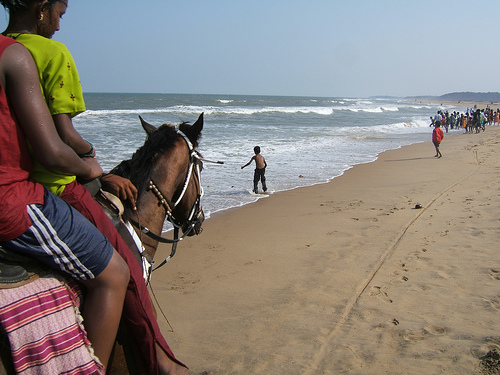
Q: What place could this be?
A: It is a beach.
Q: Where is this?
A: This is at the beach.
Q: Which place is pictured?
A: It is a beach.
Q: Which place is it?
A: It is a beach.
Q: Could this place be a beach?
A: Yes, it is a beach.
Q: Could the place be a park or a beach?
A: It is a beach.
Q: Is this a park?
A: No, it is a beach.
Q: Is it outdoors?
A: Yes, it is outdoors.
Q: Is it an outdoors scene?
A: Yes, it is outdoors.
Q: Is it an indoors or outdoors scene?
A: It is outdoors.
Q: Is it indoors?
A: No, it is outdoors.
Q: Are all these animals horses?
A: Yes, all the animals are horses.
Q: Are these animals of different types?
A: No, all the animals are horses.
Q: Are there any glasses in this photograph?
A: No, there are no glasses.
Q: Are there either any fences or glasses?
A: No, there are no glasses or fences.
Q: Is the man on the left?
A: Yes, the man is on the left of the image.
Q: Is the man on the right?
A: No, the man is on the left of the image.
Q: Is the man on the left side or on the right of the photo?
A: The man is on the left of the image.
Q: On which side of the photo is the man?
A: The man is on the left of the image.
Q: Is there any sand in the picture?
A: Yes, there is sand.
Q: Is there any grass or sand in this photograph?
A: Yes, there is sand.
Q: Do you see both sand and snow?
A: No, there is sand but no snow.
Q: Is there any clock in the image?
A: No, there are no clocks.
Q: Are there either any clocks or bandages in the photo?
A: No, there are no clocks or bandages.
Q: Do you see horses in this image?
A: Yes, there is a horse.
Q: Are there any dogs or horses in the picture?
A: Yes, there is a horse.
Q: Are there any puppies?
A: No, there are no puppies.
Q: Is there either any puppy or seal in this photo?
A: No, there are no puppies or seals.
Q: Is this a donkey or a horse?
A: This is a horse.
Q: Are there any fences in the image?
A: No, there are no fences.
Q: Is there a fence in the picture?
A: No, there are no fences.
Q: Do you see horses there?
A: Yes, there is a horse.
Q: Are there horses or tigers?
A: Yes, there is a horse.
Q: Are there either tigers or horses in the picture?
A: Yes, there is a horse.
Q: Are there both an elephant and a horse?
A: No, there is a horse but no elephants.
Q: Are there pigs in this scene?
A: No, there are no pigs.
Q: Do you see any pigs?
A: No, there are no pigs.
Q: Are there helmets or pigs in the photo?
A: No, there are no pigs or helmets.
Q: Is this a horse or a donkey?
A: This is a horse.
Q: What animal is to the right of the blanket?
A: The animal is a horse.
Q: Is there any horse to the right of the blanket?
A: Yes, there is a horse to the right of the blanket.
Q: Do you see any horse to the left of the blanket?
A: No, the horse is to the right of the blanket.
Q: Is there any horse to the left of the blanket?
A: No, the horse is to the right of the blanket.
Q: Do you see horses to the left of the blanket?
A: No, the horse is to the right of the blanket.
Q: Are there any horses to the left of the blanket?
A: No, the horse is to the right of the blanket.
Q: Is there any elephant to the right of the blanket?
A: No, there is a horse to the right of the blanket.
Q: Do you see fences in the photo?
A: No, there are no fences.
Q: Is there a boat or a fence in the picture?
A: No, there are no fences or boats.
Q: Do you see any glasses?
A: No, there are no glasses.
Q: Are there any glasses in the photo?
A: No, there are no glasses.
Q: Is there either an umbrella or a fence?
A: No, there are no fences or umbrellas.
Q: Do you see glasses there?
A: No, there are no glasses.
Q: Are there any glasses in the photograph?
A: No, there are no glasses.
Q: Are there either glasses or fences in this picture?
A: No, there are no glasses or fences.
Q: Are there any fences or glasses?
A: No, there are no glasses or fences.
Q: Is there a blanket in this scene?
A: Yes, there is a blanket.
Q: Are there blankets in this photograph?
A: Yes, there is a blanket.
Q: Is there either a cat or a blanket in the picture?
A: Yes, there is a blanket.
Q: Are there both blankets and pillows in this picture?
A: No, there is a blanket but no pillows.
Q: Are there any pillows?
A: No, there are no pillows.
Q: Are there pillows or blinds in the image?
A: No, there are no pillows or blinds.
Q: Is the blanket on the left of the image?
A: Yes, the blanket is on the left of the image.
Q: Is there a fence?
A: No, there are no fences.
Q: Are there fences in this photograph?
A: No, there are no fences.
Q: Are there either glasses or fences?
A: No, there are no fences or glasses.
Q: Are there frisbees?
A: No, there are no frisbees.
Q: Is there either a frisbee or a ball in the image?
A: No, there are no frisbees or balls.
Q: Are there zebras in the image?
A: No, there are no zebras.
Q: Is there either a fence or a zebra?
A: No, there are no zebras or fences.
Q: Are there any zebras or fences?
A: No, there are no zebras or fences.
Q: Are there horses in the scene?
A: Yes, there is a horse.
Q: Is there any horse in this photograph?
A: Yes, there is a horse.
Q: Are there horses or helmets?
A: Yes, there is a horse.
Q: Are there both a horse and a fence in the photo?
A: No, there is a horse but no fences.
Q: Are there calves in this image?
A: No, there are no calves.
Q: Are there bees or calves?
A: No, there are no calves or bees.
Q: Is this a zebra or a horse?
A: This is a horse.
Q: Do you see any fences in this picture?
A: No, there are no fences.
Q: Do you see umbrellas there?
A: No, there are no umbrellas.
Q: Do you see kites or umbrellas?
A: No, there are no umbrellas or kites.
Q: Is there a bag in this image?
A: No, there are no bags.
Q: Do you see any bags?
A: No, there are no bags.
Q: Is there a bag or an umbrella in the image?
A: No, there are no bags or umbrellas.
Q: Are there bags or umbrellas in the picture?
A: No, there are no bags or umbrellas.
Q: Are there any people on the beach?
A: Yes, there are people on the beach.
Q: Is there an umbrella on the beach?
A: No, there are people on the beach.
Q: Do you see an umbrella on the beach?
A: No, there are people on the beach.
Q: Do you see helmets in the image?
A: No, there are no helmets.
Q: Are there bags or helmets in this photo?
A: No, there are no helmets or bags.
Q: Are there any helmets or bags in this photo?
A: No, there are no helmets or bags.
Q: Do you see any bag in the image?
A: No, there are no bags.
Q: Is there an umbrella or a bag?
A: No, there are no bags or umbrellas.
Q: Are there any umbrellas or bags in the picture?
A: No, there are no bags or umbrellas.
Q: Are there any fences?
A: No, there are no fences.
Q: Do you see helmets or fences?
A: No, there are no fences or helmets.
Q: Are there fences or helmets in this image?
A: No, there are no fences or helmets.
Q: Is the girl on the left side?
A: Yes, the girl is on the left of the image.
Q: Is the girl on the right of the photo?
A: No, the girl is on the left of the image.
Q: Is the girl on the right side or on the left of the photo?
A: The girl is on the left of the image.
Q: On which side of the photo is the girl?
A: The girl is on the left of the image.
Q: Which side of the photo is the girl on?
A: The girl is on the left of the image.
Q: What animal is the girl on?
A: The girl is on the horse.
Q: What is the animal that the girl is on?
A: The animal is a horse.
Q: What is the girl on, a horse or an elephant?
A: The girl is on a horse.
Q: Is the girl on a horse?
A: Yes, the girl is on a horse.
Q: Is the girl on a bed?
A: No, the girl is on a horse.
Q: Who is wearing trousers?
A: The girl is wearing trousers.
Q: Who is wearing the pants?
A: The girl is wearing trousers.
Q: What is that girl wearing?
A: The girl is wearing trousers.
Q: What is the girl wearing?
A: The girl is wearing trousers.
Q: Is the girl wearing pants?
A: Yes, the girl is wearing pants.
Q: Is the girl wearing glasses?
A: No, the girl is wearing pants.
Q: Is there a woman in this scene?
A: Yes, there is a woman.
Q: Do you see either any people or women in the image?
A: Yes, there is a woman.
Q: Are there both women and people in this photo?
A: Yes, there are both a woman and a person.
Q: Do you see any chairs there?
A: No, there are no chairs.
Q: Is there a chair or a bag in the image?
A: No, there are no chairs or bags.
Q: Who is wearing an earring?
A: The woman is wearing an earring.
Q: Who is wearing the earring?
A: The woman is wearing an earring.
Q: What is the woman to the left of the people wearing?
A: The woman is wearing an earring.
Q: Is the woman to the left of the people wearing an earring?
A: Yes, the woman is wearing an earring.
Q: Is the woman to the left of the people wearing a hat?
A: No, the woman is wearing an earring.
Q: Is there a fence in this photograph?
A: No, there are no fences.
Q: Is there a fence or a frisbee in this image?
A: No, there are no fences or frisbees.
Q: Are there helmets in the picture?
A: No, there are no helmets.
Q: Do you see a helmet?
A: No, there are no helmets.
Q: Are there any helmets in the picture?
A: No, there are no helmets.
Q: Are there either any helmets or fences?
A: No, there are no helmets or fences.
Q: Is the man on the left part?
A: Yes, the man is on the left of the image.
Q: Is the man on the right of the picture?
A: No, the man is on the left of the image.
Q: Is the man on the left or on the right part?
A: The man is on the left of the image.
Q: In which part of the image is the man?
A: The man is on the left of the image.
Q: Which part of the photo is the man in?
A: The man is on the left of the image.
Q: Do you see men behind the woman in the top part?
A: Yes, there is a man behind the woman.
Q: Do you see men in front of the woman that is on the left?
A: No, the man is behind the woman.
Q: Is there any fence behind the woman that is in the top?
A: No, there is a man behind the woman.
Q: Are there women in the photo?
A: Yes, there is a woman.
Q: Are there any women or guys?
A: Yes, there is a woman.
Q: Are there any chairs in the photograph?
A: No, there are no chairs.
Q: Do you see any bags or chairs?
A: No, there are no chairs or bags.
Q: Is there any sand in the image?
A: Yes, there is sand.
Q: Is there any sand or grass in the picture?
A: Yes, there is sand.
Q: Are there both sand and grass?
A: No, there is sand but no grass.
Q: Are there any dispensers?
A: No, there are no dispensers.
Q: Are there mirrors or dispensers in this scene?
A: No, there are no dispensers or mirrors.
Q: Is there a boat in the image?
A: No, there are no boats.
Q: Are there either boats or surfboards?
A: No, there are no boats or surfboards.